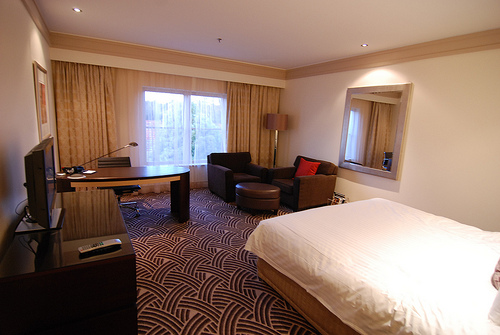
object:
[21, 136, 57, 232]
television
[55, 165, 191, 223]
brown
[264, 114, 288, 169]
lapm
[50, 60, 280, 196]
curtains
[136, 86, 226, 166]
window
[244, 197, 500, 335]
bed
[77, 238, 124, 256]
controller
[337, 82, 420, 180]
mirror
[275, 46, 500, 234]
wall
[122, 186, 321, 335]
carpet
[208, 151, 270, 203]
armchairs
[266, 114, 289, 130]
lamp shade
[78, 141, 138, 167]
lamp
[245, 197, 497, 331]
sheet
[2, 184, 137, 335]
desk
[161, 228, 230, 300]
design